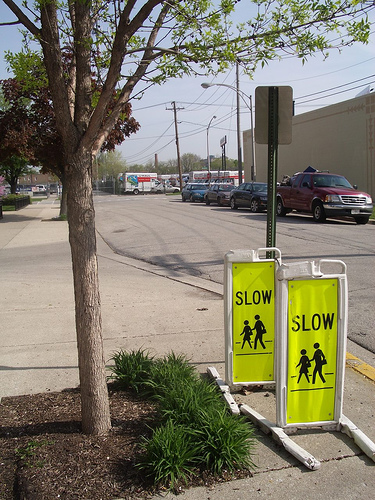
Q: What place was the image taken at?
A: It was taken at the street.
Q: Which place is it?
A: It is a street.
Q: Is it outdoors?
A: Yes, it is outdoors.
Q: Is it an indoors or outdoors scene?
A: It is outdoors.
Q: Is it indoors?
A: No, it is outdoors.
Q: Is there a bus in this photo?
A: No, there are no buses.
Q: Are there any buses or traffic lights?
A: No, there are no buses or traffic lights.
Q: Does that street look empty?
A: Yes, the street is empty.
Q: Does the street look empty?
A: Yes, the street is empty.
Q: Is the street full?
A: No, the street is empty.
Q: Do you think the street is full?
A: No, the street is empty.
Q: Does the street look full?
A: No, the street is empty.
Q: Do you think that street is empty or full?
A: The street is empty.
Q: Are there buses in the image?
A: No, there are no buses.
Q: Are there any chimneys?
A: No, there are no chimneys.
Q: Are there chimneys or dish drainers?
A: No, there are no chimneys or dish drainers.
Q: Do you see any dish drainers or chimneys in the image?
A: No, there are no chimneys or dish drainers.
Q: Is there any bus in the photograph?
A: No, there are no buses.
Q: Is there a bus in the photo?
A: No, there are no buses.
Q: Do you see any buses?
A: No, there are no buses.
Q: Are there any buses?
A: No, there are no buses.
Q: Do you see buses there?
A: No, there are no buses.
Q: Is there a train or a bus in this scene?
A: No, there are no buses or trains.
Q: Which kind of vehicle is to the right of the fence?
A: The vehicles are cars.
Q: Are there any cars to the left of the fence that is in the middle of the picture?
A: No, the cars are to the right of the fence.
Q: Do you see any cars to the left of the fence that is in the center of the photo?
A: No, the cars are to the right of the fence.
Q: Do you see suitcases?
A: No, there are no suitcases.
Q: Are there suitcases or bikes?
A: No, there are no suitcases or bikes.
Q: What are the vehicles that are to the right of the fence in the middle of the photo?
A: The vehicles are cars.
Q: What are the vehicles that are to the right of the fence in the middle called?
A: The vehicles are cars.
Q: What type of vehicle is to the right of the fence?
A: The vehicles are cars.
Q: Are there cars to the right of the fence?
A: Yes, there are cars to the right of the fence.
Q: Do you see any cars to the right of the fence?
A: Yes, there are cars to the right of the fence.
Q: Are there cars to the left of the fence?
A: No, the cars are to the right of the fence.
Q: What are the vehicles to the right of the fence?
A: The vehicles are cars.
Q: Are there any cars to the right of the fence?
A: Yes, there are cars to the right of the fence.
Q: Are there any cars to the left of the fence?
A: No, the cars are to the right of the fence.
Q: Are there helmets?
A: No, there are no helmets.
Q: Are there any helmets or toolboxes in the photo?
A: No, there are no helmets or toolboxes.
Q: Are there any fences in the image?
A: Yes, there is a fence.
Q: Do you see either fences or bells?
A: Yes, there is a fence.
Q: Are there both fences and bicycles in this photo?
A: No, there is a fence but no bikes.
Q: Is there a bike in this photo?
A: No, there are no bikes.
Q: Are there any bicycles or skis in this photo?
A: No, there are no bicycles or skis.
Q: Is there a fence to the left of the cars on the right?
A: Yes, there is a fence to the left of the cars.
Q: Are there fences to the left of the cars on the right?
A: Yes, there is a fence to the left of the cars.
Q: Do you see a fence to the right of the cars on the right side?
A: No, the fence is to the left of the cars.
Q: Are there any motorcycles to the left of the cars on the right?
A: No, there is a fence to the left of the cars.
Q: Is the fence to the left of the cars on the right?
A: Yes, the fence is to the left of the cars.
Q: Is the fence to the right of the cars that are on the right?
A: No, the fence is to the left of the cars.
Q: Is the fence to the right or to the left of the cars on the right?
A: The fence is to the left of the cars.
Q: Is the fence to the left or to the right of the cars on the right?
A: The fence is to the left of the cars.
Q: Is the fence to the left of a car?
A: Yes, the fence is to the left of a car.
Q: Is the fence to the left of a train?
A: No, the fence is to the left of a car.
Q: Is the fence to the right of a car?
A: No, the fence is to the left of a car.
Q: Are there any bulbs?
A: No, there are no bulbs.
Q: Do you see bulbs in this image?
A: No, there are no bulbs.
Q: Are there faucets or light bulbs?
A: No, there are no light bulbs or faucets.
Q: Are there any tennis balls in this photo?
A: No, there are no tennis balls.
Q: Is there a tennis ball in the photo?
A: No, there are no tennis balls.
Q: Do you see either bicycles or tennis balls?
A: No, there are no tennis balls or bicycles.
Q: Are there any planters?
A: No, there are no planters.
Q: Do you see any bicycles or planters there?
A: No, there are no planters or bicycles.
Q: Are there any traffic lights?
A: No, there are no traffic lights.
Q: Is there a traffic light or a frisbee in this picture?
A: No, there are no traffic lights or frisbees.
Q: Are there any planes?
A: No, there are no planes.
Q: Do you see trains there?
A: No, there are no trains.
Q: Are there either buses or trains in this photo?
A: No, there are no trains or buses.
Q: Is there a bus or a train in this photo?
A: No, there are no trains or buses.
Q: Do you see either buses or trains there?
A: No, there are no trains or buses.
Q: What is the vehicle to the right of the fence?
A: The vehicle is a car.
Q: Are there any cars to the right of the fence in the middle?
A: Yes, there is a car to the right of the fence.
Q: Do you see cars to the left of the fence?
A: No, the car is to the right of the fence.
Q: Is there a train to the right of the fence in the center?
A: No, there is a car to the right of the fence.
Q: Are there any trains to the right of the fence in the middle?
A: No, there is a car to the right of the fence.